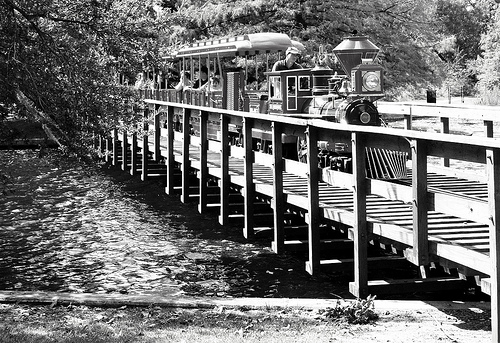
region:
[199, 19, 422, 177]
small train on track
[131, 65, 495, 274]
wooden fence along track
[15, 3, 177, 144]
trees are overhanging fence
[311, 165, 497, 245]
train on wooden tracks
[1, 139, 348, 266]
water is beneath bridge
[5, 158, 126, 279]
small ripples on water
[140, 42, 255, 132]
small trolley on train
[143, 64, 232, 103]
people sitting in train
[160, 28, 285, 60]
light roof on trolley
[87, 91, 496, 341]
bridge made of wood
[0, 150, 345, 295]
water near the bridge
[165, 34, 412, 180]
train on the bridge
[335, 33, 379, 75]
chimney of the train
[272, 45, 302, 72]
man driving the train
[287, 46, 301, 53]
the hat is white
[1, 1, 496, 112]
trees are in the background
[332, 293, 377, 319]
a weed on the ground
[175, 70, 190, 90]
person riding the train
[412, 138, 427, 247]
THIS IS A POLE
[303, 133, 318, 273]
THIS IS A POLE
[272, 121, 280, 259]
THIS IS A POLE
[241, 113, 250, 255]
THIS IS A POLE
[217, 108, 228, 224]
THIS IS A POLE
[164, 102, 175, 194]
THIS IS A POLE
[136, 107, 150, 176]
THIS IS A POLE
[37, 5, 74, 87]
BRANCHES OF A TREE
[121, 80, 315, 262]
the background color is black and white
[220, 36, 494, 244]
view is at a railway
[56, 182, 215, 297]
the fllor is muddy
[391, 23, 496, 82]
trees are at the far end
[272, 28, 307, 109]
a man is driving the train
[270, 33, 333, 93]
the man driving is wearing a cape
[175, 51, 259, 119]
people are in the train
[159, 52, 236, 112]
people are looking outside th window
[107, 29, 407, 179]
the train on the bridge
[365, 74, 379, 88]
the light on the train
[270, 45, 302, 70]
the guy on the train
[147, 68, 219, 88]
the people on the train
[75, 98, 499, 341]
the bridge the train is on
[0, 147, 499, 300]
the water under the bridge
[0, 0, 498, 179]
the trees around the bridge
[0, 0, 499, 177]
the trees around the train tracks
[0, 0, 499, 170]
the trees on both sides of the track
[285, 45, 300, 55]
the hat on the man on the train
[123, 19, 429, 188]
train on the tracks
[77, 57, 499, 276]
railing next to train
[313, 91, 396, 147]
engine on the train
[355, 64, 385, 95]
light on the train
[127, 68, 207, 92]
people on the train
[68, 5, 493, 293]
train on a bridge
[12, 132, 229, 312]
a body of water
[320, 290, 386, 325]
weeds on the ground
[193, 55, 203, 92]
pole on the train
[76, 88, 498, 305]
A long wooden bridge.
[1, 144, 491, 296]
A grey body of rippled water.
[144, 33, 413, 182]
A long train with big stack on top.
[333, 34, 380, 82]
Large metal stack on a train front.